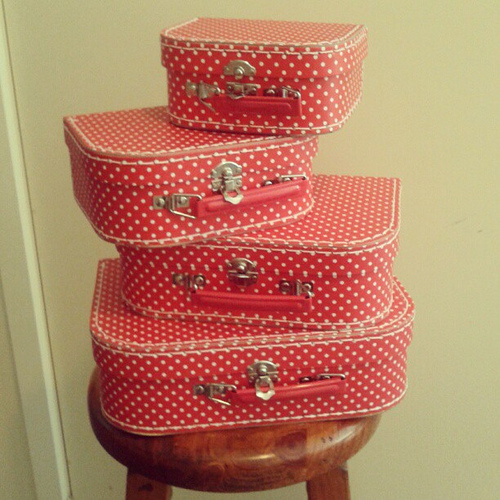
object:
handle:
[193, 181, 302, 217]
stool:
[85, 364, 384, 499]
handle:
[228, 378, 345, 407]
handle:
[193, 280, 302, 308]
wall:
[0, 0, 498, 499]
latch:
[218, 59, 258, 82]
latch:
[208, 159, 247, 205]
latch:
[221, 256, 257, 286]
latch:
[245, 360, 279, 400]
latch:
[313, 369, 349, 383]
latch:
[293, 287, 314, 300]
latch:
[186, 274, 208, 294]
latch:
[166, 190, 204, 220]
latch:
[279, 173, 312, 188]